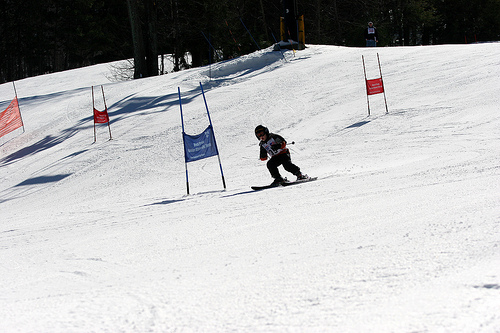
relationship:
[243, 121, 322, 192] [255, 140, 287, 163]
contestant wearing bib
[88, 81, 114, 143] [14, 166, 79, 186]
marker casting off shadow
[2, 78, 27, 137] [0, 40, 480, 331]
fence marking course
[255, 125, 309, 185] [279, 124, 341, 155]
contestant holding sticks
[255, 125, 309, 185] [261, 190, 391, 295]
contestant skiing snow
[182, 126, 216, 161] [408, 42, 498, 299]
sign on hill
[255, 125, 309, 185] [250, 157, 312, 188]
contestant on ski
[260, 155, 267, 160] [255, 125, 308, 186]
hand on person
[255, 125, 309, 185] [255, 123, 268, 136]
contestant wearing hat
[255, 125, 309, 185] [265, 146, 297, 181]
contestant wearing dark pant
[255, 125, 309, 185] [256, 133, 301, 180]
contestant wears clothes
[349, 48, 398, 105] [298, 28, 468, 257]
sign on hill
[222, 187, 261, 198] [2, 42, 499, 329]
shadow on snow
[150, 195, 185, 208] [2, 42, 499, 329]
shadow on snow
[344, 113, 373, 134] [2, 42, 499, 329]
shadow on snow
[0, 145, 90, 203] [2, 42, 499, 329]
shadow on snow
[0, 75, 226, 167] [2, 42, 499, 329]
shadow on snow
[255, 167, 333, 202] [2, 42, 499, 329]
skis on snow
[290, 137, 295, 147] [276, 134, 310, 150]
tip of a pole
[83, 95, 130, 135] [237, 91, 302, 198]
gate to guide skiers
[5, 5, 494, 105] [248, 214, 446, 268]
trees beyond snow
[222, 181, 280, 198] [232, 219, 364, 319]
shadow on snow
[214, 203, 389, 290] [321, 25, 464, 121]
snow covered hillside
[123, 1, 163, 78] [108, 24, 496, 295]
trunk on hill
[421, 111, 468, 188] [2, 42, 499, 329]
marks on snow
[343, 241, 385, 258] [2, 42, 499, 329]
marks on snow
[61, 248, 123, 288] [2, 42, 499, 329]
marks on snow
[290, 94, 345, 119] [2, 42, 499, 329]
marks on snow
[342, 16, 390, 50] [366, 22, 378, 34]
skier with a bib